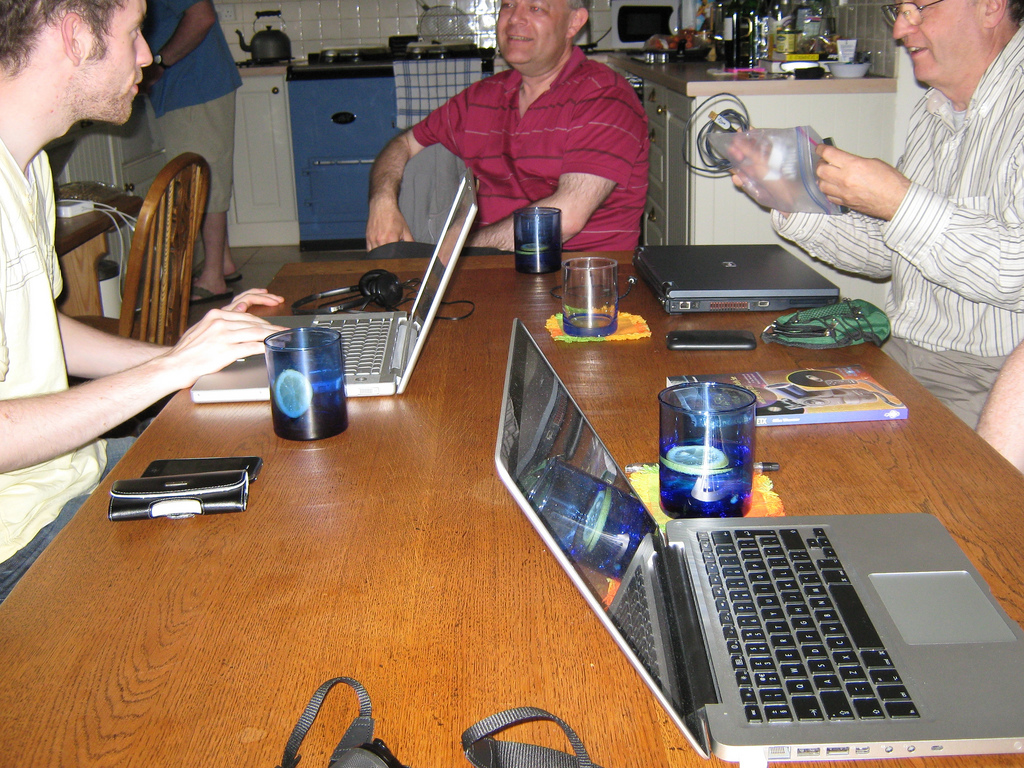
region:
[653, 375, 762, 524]
A GLASS OF WATER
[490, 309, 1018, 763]
AN OPEN LAPTOP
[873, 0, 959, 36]
A PAIR OF GLASSES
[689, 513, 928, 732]
BLACK LAPTOP KEYS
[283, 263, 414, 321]
A PAIR OF HEADPHONES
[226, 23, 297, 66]
A METAL TEA POT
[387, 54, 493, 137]
A BLUE AND WHITE KITCHEN TOWEL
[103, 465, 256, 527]
A BLACK CELL PHONE CASE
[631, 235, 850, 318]
A CLOSED LAPTOP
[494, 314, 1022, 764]
an open laptop computer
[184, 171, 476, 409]
an open laptop computer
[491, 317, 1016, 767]
an Apple MacBook Pro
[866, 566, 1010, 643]
a computer track pad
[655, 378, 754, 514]
a blue drinking glass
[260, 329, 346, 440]
a blue drinking glass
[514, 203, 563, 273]
a blue drinking glass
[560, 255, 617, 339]
a blue drinking glass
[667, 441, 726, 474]
a slice of lemon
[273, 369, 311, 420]
a slice of lemon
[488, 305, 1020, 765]
Laptop is on a table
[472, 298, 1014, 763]
Laptop on a wooden table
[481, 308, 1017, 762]
Laptop is on a wooden table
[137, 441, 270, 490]
Phone on a table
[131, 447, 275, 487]
Phone is on a table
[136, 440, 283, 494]
Cell phone on a table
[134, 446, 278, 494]
Cell phone is on a table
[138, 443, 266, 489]
Cell phone on a wooden table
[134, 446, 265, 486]
Cell phone is on a wooden table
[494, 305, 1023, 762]
Silver laptop with black keyboard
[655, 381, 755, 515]
Blue glass on top of coaster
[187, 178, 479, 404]
White laptop computer on table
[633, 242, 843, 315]
Dark grey laptop computer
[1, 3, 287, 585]
Man with a white t-shirt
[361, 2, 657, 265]
Man wearing burgundy shirt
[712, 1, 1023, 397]
Man wearing glasses and white striped shirt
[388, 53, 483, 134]
Blue and white striped towel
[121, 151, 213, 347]
Wooden chair by table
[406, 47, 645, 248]
the shirt is red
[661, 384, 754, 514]
the cup is blue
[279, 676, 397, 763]
the thing is gray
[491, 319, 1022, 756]
the laptop is gray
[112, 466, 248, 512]
black and white case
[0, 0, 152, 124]
head of a guy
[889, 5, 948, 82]
face of a man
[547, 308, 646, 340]
the napkin is colorful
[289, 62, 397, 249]
the machine is blue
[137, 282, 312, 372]
the hand of a man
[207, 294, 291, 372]
the fingers of a man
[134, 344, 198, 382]
the wrist of a man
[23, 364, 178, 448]
the arm of a man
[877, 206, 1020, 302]
the sleeve of a man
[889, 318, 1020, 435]
the pants of a man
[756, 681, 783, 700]
black key on the silver laptop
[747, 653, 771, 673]
black key on the silver laptop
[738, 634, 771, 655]
black key on the silver laptop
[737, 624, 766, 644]
black key on the silver laptop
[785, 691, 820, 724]
black key on the silver laptop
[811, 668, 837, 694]
black key on the silver laptop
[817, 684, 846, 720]
black key on the silver laptop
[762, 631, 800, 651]
black key on the silver laptop